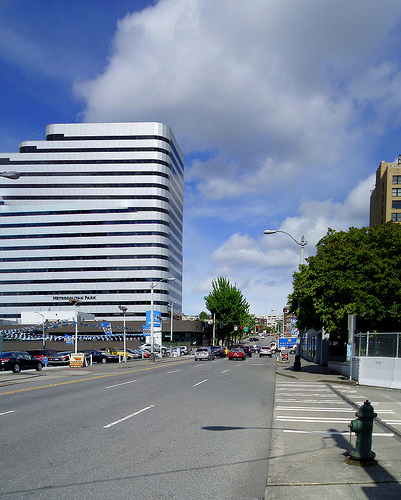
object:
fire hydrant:
[345, 396, 378, 461]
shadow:
[326, 424, 401, 500]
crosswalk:
[273, 406, 358, 410]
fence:
[353, 331, 401, 392]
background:
[0, 0, 401, 499]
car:
[227, 346, 247, 361]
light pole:
[300, 234, 306, 265]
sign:
[70, 353, 86, 368]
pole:
[74, 309, 78, 353]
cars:
[193, 347, 216, 361]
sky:
[0, 0, 399, 318]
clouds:
[0, 0, 401, 316]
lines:
[102, 403, 156, 428]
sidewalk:
[262, 353, 401, 500]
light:
[240, 326, 243, 330]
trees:
[285, 221, 401, 356]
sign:
[279, 338, 297, 349]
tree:
[204, 275, 255, 349]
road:
[0, 333, 277, 500]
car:
[0, 348, 46, 374]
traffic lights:
[256, 325, 259, 332]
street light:
[263, 226, 279, 236]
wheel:
[36, 363, 43, 372]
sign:
[244, 326, 249, 331]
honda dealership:
[0, 117, 186, 321]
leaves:
[356, 264, 361, 269]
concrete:
[265, 373, 400, 500]